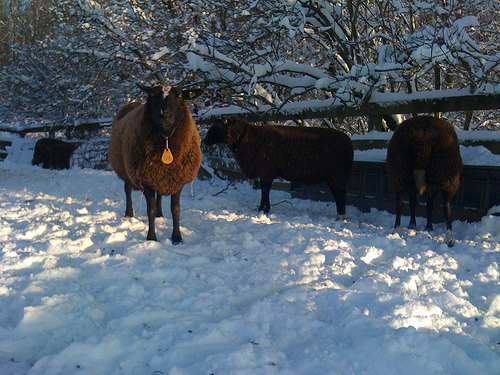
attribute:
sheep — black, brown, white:
[202, 114, 380, 226]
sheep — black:
[203, 116, 360, 215]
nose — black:
[156, 109, 179, 127]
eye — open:
[146, 89, 158, 106]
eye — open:
[171, 90, 183, 102]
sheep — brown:
[199, 110, 355, 216]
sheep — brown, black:
[384, 112, 466, 233]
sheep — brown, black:
[94, 49, 228, 229]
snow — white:
[4, 170, 498, 370]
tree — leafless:
[8, 4, 459, 121]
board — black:
[108, 70, 218, 240]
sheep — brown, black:
[96, 75, 226, 251]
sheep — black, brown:
[378, 112, 463, 246]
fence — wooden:
[2, 87, 499, 227]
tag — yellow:
[161, 149, 221, 191]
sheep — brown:
[107, 82, 204, 244]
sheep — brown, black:
[94, 77, 201, 242]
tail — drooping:
[410, 137, 430, 204]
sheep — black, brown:
[202, 106, 355, 225]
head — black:
[135, 79, 205, 139]